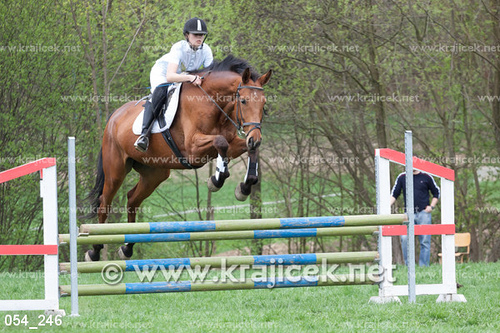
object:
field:
[0, 0, 499, 332]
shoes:
[204, 177, 225, 192]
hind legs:
[92, 163, 130, 249]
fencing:
[0, 129, 467, 323]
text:
[99, 257, 398, 288]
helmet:
[182, 17, 209, 37]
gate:
[366, 147, 469, 304]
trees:
[0, 0, 229, 274]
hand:
[422, 206, 433, 213]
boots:
[137, 100, 165, 151]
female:
[137, 16, 214, 151]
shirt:
[390, 170, 441, 213]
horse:
[78, 54, 273, 261]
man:
[390, 152, 441, 267]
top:
[389, 168, 441, 214]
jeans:
[399, 209, 432, 265]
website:
[132, 257, 397, 289]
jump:
[77, 16, 273, 261]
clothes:
[148, 39, 215, 95]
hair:
[203, 53, 261, 83]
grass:
[0, 262, 499, 332]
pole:
[79, 213, 408, 235]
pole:
[59, 273, 380, 296]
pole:
[57, 224, 379, 244]